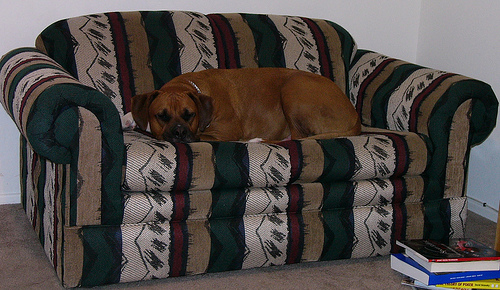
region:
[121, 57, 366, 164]
the dog is brown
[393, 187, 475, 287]
books on the floor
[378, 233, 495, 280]
books on the floor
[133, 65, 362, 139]
the dog lying on the couch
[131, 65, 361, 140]
the large dog lying on the couch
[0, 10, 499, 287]
the sofa along the wall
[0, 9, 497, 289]
the sofa under the dog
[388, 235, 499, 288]
the stack of books on the ground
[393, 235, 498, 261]
the book at the top of the stack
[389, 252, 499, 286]
the blue book in the stack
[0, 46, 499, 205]
the armrest on the couch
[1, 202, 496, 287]
the carpet on the ground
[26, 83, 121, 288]
the green fabric on the front of the arm rest and the couch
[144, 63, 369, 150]
A large brown dog lying on the couch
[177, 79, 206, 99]
A silver collar around the dog's neck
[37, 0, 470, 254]
A multicolored couch beneath the dog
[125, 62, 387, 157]
The dog is resting on the sofa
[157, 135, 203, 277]
A red stripe on the sofa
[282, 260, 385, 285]
A grey carpet beneath the couch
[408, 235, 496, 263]
A small red book by the couch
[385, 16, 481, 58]
A blank white wall behind the couch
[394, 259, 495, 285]
A thick blue book in the book stack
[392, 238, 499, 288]
A stack of books on the floor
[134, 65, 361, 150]
A brwon dog on the couch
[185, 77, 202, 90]
A silver chain on the dogs neck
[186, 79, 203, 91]
A collar on the brown dog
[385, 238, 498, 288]
A stack of books on the ground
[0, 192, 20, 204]
A white baseboard for the wall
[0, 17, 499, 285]
A green, red,white,a nd brown stripped couch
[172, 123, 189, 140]
The black nose of the dog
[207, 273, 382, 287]
The light brown colored carpet on the ground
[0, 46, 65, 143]
The arm of the colored couch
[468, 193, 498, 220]
A wire alont he base board of the wall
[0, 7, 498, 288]
bullmastiff resting on loveseat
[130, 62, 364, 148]
red dog with black mask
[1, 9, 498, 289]
large dog on loveseat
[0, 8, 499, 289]
black, white, tan and red loveseat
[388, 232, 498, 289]
stack of books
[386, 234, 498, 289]
blue book in stack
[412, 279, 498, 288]
yellow book in stack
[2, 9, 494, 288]
loveseat on brown carpet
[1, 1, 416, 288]
loveseat in front of white wall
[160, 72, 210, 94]
collar around dog's neck